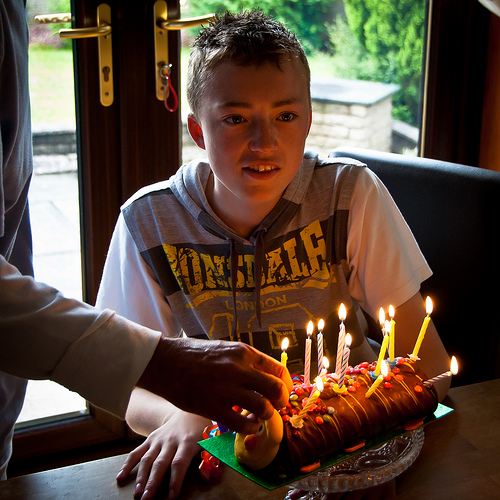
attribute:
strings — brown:
[222, 235, 269, 327]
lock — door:
[50, 1, 122, 111]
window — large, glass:
[28, 2, 80, 295]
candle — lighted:
[280, 336, 290, 366]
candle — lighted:
[302, 320, 312, 382]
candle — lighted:
[192, 279, 458, 386]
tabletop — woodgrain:
[0, 378, 499, 499]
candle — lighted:
[368, 320, 393, 379]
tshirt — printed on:
[94, 152, 442, 384]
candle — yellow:
[290, 383, 314, 410]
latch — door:
[156, 59, 173, 100]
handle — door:
[58, 5, 113, 106]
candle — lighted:
[423, 355, 460, 384]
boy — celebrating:
[78, 6, 473, 496]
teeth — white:
[245, 162, 280, 173]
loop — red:
[162, 74, 178, 112]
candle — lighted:
[320, 301, 398, 374]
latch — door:
[100, 63, 111, 92]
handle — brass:
[58, 23, 110, 42]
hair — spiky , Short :
[183, 10, 314, 100]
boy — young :
[110, 9, 460, 497]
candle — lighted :
[334, 331, 362, 384]